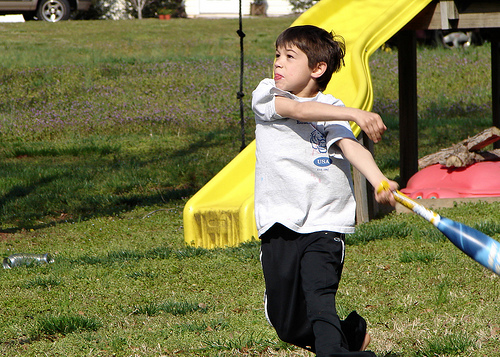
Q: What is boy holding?
A: Bat.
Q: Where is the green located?
A: Grass.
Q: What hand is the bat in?
A: Left.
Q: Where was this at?
A: Park.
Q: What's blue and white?
A: Bat.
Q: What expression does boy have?
A: Smile.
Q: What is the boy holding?
A: Bat.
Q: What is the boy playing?
A: Baseball.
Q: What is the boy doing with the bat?
A: Swinging it.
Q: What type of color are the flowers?
A: Purple.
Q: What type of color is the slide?
A: Yellow.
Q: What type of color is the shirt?
A: White.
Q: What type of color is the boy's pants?
A: Black.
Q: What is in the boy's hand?
A: Bat.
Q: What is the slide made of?
A: Plastic.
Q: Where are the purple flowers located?
A: In the grass.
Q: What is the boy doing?
A: Swinging the baseball bat.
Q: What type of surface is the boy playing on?
A: Green grass.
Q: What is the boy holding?
A: A bat.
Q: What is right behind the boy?
A: A slide.